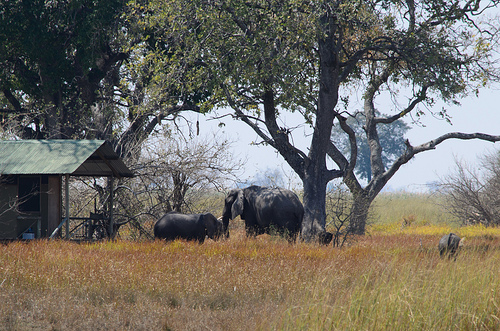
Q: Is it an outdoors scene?
A: Yes, it is outdoors.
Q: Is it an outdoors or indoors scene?
A: It is outdoors.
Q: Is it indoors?
A: No, it is outdoors.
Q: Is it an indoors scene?
A: No, it is outdoors.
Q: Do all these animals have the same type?
A: Yes, all the animals are elephants.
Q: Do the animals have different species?
A: No, all the animals are elephants.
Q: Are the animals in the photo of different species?
A: No, all the animals are elephants.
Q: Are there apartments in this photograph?
A: No, there are no apartments.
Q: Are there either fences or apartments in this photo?
A: No, there are no apartments or fences.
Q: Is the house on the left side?
A: Yes, the house is on the left of the image.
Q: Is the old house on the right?
A: No, the house is on the left of the image.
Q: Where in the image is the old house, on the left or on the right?
A: The house is on the left of the image.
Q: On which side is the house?
A: The house is on the left of the image.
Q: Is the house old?
A: Yes, the house is old.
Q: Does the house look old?
A: Yes, the house is old.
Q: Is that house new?
A: No, the house is old.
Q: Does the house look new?
A: No, the house is old.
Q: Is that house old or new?
A: The house is old.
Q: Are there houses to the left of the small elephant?
A: Yes, there is a house to the left of the elephant.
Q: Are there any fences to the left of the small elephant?
A: No, there is a house to the left of the elephant.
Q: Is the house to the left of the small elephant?
A: Yes, the house is to the left of the elephant.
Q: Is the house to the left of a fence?
A: No, the house is to the left of the elephant.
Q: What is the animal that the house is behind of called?
A: The animal is an elephant.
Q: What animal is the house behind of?
A: The house is behind the elephant.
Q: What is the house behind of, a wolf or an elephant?
A: The house is behind an elephant.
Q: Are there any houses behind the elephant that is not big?
A: Yes, there is a house behind the elephant.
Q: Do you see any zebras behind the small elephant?
A: No, there is a house behind the elephant.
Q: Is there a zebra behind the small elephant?
A: No, there is a house behind the elephant.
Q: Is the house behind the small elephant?
A: Yes, the house is behind the elephant.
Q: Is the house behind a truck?
A: No, the house is behind the elephant.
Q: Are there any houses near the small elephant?
A: Yes, there is a house near the elephant.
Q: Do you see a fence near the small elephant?
A: No, there is a house near the elephant.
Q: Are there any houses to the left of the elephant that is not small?
A: Yes, there is a house to the left of the elephant.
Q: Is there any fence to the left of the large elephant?
A: No, there is a house to the left of the elephant.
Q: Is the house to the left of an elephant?
A: Yes, the house is to the left of an elephant.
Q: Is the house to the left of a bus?
A: No, the house is to the left of an elephant.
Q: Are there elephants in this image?
A: Yes, there is an elephant.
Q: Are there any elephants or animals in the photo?
A: Yes, there is an elephant.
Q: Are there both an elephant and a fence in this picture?
A: No, there is an elephant but no fences.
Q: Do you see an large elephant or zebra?
A: Yes, there is a large elephant.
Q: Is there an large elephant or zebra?
A: Yes, there is a large elephant.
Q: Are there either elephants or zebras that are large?
A: Yes, the elephant is large.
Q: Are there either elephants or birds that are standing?
A: Yes, the elephant is standing.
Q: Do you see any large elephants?
A: Yes, there is a large elephant.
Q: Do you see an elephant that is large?
A: Yes, there is an elephant that is large.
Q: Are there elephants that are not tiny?
A: Yes, there is a large elephant.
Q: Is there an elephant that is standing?
A: Yes, there is an elephant that is standing.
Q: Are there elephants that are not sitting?
A: Yes, there is an elephant that is standing.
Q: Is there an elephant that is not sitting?
A: Yes, there is an elephant that is standing.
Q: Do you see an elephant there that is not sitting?
A: Yes, there is an elephant that is standing .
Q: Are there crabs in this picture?
A: No, there are no crabs.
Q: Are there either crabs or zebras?
A: No, there are no crabs or zebras.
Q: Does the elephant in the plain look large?
A: Yes, the elephant is large.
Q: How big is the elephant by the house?
A: The elephant is large.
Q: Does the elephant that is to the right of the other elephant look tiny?
A: No, the elephant is large.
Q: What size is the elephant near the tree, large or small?
A: The elephant is large.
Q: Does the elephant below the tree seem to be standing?
A: Yes, the elephant is standing.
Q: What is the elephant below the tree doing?
A: The elephant is standing.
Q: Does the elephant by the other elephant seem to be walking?
A: No, the elephant is standing.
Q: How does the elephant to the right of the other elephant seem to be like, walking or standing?
A: The elephant is standing.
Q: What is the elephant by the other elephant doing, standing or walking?
A: The elephant is standing.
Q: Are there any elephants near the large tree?
A: Yes, there is an elephant near the tree.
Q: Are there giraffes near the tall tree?
A: No, there is an elephant near the tree.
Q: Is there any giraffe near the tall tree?
A: No, there is an elephant near the tree.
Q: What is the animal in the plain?
A: The animal is an elephant.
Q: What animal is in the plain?
A: The animal is an elephant.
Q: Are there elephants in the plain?
A: Yes, there is an elephant in the plain.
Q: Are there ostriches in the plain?
A: No, there is an elephant in the plain.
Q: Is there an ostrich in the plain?
A: No, there is an elephant in the plain.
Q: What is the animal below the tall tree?
A: The animal is an elephant.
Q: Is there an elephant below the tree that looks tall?
A: Yes, there is an elephant below the tree.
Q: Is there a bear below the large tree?
A: No, there is an elephant below the tree.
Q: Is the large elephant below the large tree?
A: Yes, the elephant is below the tree.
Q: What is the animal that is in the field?
A: The animal is an elephant.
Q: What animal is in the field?
A: The animal is an elephant.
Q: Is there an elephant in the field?
A: Yes, there is an elephant in the field.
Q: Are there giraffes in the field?
A: No, there is an elephant in the field.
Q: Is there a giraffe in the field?
A: No, there is an elephant in the field.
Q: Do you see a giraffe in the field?
A: No, there is an elephant in the field.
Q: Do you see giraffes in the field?
A: No, there is an elephant in the field.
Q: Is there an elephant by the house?
A: Yes, there is an elephant by the house.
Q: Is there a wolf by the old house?
A: No, there is an elephant by the house.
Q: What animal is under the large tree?
A: The elephant is under the tree.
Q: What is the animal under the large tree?
A: The animal is an elephant.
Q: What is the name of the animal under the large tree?
A: The animal is an elephant.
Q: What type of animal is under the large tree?
A: The animal is an elephant.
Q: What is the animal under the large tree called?
A: The animal is an elephant.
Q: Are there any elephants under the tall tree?
A: Yes, there is an elephant under the tree.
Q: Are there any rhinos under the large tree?
A: No, there is an elephant under the tree.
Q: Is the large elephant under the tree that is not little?
A: Yes, the elephant is under the tree.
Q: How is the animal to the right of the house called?
A: The animal is an elephant.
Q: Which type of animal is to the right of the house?
A: The animal is an elephant.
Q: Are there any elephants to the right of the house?
A: Yes, there is an elephant to the right of the house.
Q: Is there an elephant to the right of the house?
A: Yes, there is an elephant to the right of the house.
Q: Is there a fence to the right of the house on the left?
A: No, there is an elephant to the right of the house.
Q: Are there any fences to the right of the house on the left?
A: No, there is an elephant to the right of the house.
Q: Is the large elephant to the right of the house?
A: Yes, the elephant is to the right of the house.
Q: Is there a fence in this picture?
A: No, there are no fences.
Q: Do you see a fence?
A: No, there are no fences.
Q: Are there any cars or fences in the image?
A: No, there are no fences or cars.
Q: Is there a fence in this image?
A: No, there are no fences.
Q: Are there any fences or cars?
A: No, there are no fences or cars.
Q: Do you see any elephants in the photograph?
A: Yes, there is an elephant.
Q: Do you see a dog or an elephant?
A: Yes, there is an elephant.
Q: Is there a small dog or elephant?
A: Yes, there is a small elephant.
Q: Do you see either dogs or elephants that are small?
A: Yes, the elephant is small.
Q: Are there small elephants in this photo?
A: Yes, there is a small elephant.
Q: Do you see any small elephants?
A: Yes, there is a small elephant.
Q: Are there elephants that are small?
A: Yes, there is an elephant that is small.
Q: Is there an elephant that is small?
A: Yes, there is an elephant that is small.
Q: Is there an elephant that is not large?
A: Yes, there is a small elephant.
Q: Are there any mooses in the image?
A: No, there are no mooses.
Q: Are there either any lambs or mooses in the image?
A: No, there are no mooses or lambs.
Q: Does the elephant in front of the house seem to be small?
A: Yes, the elephant is small.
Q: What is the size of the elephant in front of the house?
A: The elephant is small.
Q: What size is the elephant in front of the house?
A: The elephant is small.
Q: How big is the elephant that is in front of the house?
A: The elephant is small.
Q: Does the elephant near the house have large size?
A: No, the elephant is small.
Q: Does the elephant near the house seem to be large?
A: No, the elephant is small.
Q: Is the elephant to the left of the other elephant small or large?
A: The elephant is small.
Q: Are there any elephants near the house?
A: Yes, there is an elephant near the house.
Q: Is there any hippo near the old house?
A: No, there is an elephant near the house.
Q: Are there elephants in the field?
A: Yes, there is an elephant in the field.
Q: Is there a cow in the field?
A: No, there is an elephant in the field.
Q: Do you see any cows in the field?
A: No, there is an elephant in the field.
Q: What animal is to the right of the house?
A: The animal is an elephant.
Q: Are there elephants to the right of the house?
A: Yes, there is an elephant to the right of the house.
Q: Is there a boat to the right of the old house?
A: No, there is an elephant to the right of the house.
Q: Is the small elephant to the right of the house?
A: Yes, the elephant is to the right of the house.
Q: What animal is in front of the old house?
A: The elephant is in front of the house.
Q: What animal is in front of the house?
A: The elephant is in front of the house.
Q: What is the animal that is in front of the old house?
A: The animal is an elephant.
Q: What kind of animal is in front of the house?
A: The animal is an elephant.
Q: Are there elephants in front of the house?
A: Yes, there is an elephant in front of the house.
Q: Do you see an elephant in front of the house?
A: Yes, there is an elephant in front of the house.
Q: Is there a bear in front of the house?
A: No, there is an elephant in front of the house.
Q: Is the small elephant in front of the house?
A: Yes, the elephant is in front of the house.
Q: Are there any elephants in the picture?
A: Yes, there is an elephant.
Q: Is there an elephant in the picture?
A: Yes, there is an elephant.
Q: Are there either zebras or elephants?
A: Yes, there is an elephant.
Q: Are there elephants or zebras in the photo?
A: Yes, there is an elephant.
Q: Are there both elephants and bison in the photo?
A: No, there is an elephant but no bison.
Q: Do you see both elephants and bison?
A: No, there is an elephant but no bison.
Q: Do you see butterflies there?
A: No, there are no butterflies.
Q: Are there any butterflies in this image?
A: No, there are no butterflies.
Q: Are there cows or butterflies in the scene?
A: No, there are no butterflies or cows.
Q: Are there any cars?
A: No, there are no cars.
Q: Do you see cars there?
A: No, there are no cars.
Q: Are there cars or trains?
A: No, there are no cars or trains.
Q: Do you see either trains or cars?
A: No, there are no cars or trains.